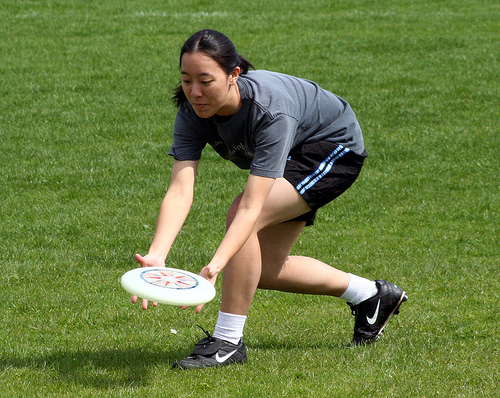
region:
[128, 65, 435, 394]
a woman standing on grass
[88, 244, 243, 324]
a white frisbee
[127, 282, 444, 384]
black and white nike sneakers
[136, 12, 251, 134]
a woman with black hair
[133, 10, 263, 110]
a woman wearing a pony tail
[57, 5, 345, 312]
a woman playing with a frisbee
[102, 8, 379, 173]
a woman wearing a gray tshirt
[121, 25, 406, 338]
a woman wearing white socks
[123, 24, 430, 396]
a woman wearing nike sneakers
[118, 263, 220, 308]
White frisbee being caught by a woman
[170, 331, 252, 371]
Black nike soccer shoe with white swosh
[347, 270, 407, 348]
Black nike soccer shoe with white swosh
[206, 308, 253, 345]
White sock on a woman catching a frisbee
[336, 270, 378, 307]
White sock on a woman catching a frisbee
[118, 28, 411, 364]
Woman about to catch a frisbee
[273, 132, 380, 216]
Black exercise shorts with double white stripe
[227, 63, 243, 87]
The left ear of a woman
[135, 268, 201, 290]
Star shape on the top of a frisbee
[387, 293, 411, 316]
Cleats on the bottom on shoes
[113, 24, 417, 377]
girl catching a frisbee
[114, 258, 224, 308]
the frisbee is white with red trim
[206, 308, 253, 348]
the young lady is wearing short white socks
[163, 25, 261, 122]
the young lady is wearing her hair back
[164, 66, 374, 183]
the young lady is wearing a gray top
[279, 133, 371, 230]
the young lady is wearing black shorts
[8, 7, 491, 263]
the grass looks healthy and well kept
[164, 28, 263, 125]
the young lady has straight black hair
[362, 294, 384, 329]
Nike is the maker of the young lady's shoes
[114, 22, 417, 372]
woman catching frisbee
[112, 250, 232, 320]
the frisbee is white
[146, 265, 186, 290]
star on the frisbee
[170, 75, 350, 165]
woman wearing t shirt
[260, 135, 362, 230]
woman wearing the shorts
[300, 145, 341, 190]
the stripe on shorts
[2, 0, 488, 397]
the lush grass is trimmed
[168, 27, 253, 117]
the head of the woman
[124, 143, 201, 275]
the arm of woman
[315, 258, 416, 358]
shoe on the foot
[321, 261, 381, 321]
sock on the shoe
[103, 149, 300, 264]
arm of the girl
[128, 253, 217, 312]
design on the Frisbee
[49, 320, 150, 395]
shadow on the ground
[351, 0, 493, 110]
a section of green grass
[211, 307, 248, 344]
a woman's white sock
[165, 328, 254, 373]
a black and white shoe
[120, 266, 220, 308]
a large Frisbee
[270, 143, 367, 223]
a woman's black and white shorts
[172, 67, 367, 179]
a woman's short sleeve gray shirt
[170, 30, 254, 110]
a woman's long black hair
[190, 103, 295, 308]
the arm of a woman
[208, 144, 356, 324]
the leg of a woman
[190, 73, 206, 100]
the nose of a woman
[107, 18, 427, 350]
the woman is catching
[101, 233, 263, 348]
this is a frisbee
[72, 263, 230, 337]
the frisbee is caught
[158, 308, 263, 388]
these are cleat shoes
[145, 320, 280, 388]
the shoes are nike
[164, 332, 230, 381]
the shoes are black and white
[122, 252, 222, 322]
the frisbee is white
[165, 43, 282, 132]
the woman is asian